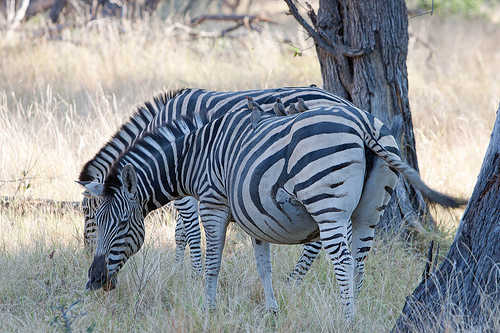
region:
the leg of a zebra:
[199, 203, 226, 319]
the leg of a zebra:
[248, 230, 283, 323]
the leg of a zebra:
[274, 232, 323, 299]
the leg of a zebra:
[316, 221, 355, 327]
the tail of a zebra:
[355, 125, 467, 208]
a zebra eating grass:
[85, 106, 470, 332]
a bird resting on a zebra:
[248, 104, 261, 129]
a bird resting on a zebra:
[273, 95, 286, 116]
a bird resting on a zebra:
[286, 100, 298, 115]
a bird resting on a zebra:
[295, 95, 311, 115]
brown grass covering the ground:
[26, 36, 111, 128]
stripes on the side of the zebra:
[201, 124, 263, 185]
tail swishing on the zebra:
[364, 130, 469, 211]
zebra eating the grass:
[76, 228, 151, 310]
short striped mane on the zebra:
[79, 122, 135, 166]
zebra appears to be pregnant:
[231, 148, 311, 250]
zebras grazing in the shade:
[51, 85, 439, 310]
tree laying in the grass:
[3, 187, 80, 222]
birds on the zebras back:
[250, 97, 317, 114]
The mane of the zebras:
[85, 110, 209, 180]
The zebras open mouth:
[92, 245, 119, 297]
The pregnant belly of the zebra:
[227, 162, 322, 247]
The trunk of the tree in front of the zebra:
[389, 143, 490, 330]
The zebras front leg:
[192, 186, 224, 331]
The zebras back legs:
[294, 147, 378, 315]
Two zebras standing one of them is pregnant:
[25, 83, 438, 328]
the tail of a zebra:
[365, 132, 478, 209]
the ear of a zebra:
[115, 158, 145, 207]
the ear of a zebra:
[69, 173, 109, 200]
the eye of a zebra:
[113, 211, 134, 233]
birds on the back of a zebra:
[234, 81, 314, 132]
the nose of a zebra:
[79, 254, 121, 295]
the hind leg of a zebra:
[289, 147, 368, 328]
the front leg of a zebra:
[193, 185, 230, 305]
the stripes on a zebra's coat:
[226, 133, 273, 213]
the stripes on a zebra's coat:
[141, 145, 181, 193]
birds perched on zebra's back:
[240, 89, 317, 127]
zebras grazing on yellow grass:
[60, 85, 390, 318]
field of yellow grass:
[9, 20, 479, 320]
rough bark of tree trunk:
[300, 12, 453, 243]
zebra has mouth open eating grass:
[82, 165, 142, 294]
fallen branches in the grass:
[29, 6, 287, 53]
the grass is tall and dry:
[10, 43, 474, 327]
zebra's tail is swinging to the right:
[368, 143, 470, 210]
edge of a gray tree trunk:
[398, 90, 496, 330]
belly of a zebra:
[228, 179, 315, 248]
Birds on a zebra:
[239, 96, 309, 126]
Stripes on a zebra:
[208, 131, 280, 191]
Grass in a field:
[136, 266, 191, 324]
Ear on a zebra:
[118, 157, 145, 208]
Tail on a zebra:
[356, 129, 473, 214]